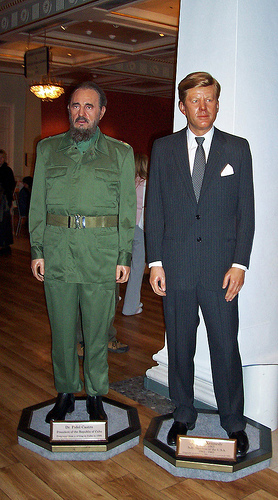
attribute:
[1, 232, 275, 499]
floor — hardwood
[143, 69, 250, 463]
statue — president kennedy, ex-president, standing, kennedy, wax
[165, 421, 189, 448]
shoe — black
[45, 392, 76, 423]
boot — black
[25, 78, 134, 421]
figure — fidel castro, ex-president, standing, wax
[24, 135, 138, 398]
uniform — green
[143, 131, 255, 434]
suit — black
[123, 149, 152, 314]
woman — blonde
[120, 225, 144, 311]
jeans — blue, gray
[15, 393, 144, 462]
base — grey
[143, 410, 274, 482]
base — grey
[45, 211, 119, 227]
belt — olive green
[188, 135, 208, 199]
tie — grey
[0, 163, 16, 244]
clothes — black